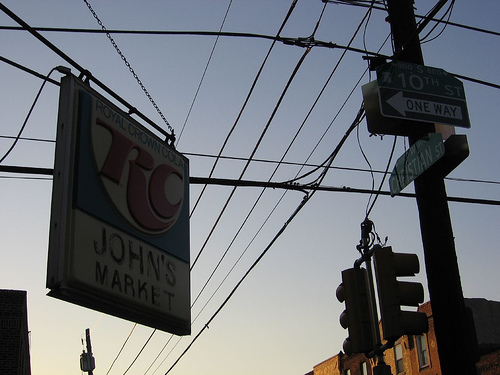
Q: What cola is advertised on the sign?
A: RC.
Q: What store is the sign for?
A: John's Market.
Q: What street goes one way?
A: 10th Street.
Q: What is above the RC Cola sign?
A: Power lines.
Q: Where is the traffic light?
A: By the street sign.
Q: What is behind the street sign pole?
A: Building.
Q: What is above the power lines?
A: Sky.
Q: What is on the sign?
A: Johns market.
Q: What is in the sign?
A: RC.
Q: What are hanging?
A: Two traffic lights.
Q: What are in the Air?
A: Powerlines.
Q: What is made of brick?
A: The building.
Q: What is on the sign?
A: A chain.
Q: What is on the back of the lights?
A: Metal.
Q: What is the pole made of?
A: Wood.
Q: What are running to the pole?
A: Wires.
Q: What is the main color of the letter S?
A: White.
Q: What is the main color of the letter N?
A: White.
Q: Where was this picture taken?
A: 10th and Christian St.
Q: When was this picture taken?
A: Daytime.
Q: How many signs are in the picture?
A: 4.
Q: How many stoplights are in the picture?
A: 2.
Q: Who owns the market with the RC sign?
A: John.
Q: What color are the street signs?
A: Green.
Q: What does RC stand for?
A: Royal Crown Cola.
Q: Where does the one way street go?
A: Left.